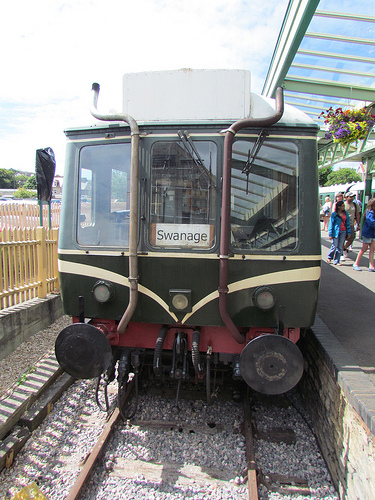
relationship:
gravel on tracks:
[80, 392, 247, 499] [66, 392, 127, 500]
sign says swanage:
[154, 221, 211, 250] [158, 229, 207, 242]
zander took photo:
[15, 480, 51, 500] [0, 1, 373, 500]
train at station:
[55, 70, 321, 417] [4, 0, 375, 497]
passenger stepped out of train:
[329, 197, 350, 266] [55, 70, 321, 417]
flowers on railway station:
[319, 100, 373, 149] [4, 0, 375, 497]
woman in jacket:
[329, 197, 350, 266] [329, 210, 351, 239]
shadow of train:
[111, 369, 351, 500] [55, 70, 321, 417]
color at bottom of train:
[93, 317, 300, 353] [55, 70, 321, 417]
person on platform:
[344, 192, 358, 256] [322, 220, 373, 296]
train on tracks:
[55, 70, 321, 417] [63, 376, 262, 499]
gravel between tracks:
[80, 392, 247, 499] [63, 376, 262, 499]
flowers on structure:
[319, 100, 373, 149] [318, 132, 372, 174]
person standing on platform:
[344, 192, 358, 256] [322, 220, 373, 296]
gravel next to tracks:
[80, 392, 247, 499] [63, 376, 262, 499]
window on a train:
[74, 140, 133, 251] [55, 70, 321, 417]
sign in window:
[154, 221, 211, 250] [137, 138, 219, 256]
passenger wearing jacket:
[329, 197, 350, 266] [329, 210, 351, 239]